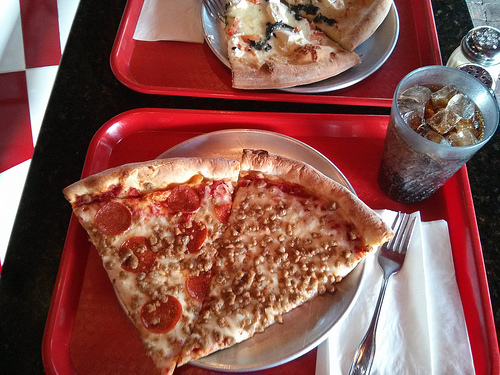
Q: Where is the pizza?
A: On plates.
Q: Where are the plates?
A: Red trays.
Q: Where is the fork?
A: On napkin.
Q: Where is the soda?
A: In cup.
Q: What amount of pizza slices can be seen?
A: Four.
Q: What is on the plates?
A: Pizza.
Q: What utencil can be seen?
A: Fork.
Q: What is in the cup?
A: Soda.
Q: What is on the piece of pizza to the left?
A: Pepperoni.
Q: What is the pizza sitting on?
A: A white plate.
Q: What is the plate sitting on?
A: A red tray.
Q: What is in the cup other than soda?
A: Ice.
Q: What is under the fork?
A: Napkins.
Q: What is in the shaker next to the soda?
A: Parmesan cheese.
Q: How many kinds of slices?
A: Two.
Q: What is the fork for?
A: Eating.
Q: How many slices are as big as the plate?
A: 1.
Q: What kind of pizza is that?
A: Looks like spinach pizza.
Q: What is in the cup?
A: Drink with ice.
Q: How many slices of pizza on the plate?
A: 2.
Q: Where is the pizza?
A: On plate.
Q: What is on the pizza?
A: Sausage crumbles.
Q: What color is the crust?
A: Brown.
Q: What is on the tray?
A: Pizza.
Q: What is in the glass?
A: Soda.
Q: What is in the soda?
A: Ice.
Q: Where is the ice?
A: In the soda.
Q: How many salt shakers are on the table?
A: 1.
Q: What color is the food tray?
A: Red.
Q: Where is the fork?
A: On top of the napkin.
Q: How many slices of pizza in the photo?
A: 4.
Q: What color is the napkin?
A: White.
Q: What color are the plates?
A: White.